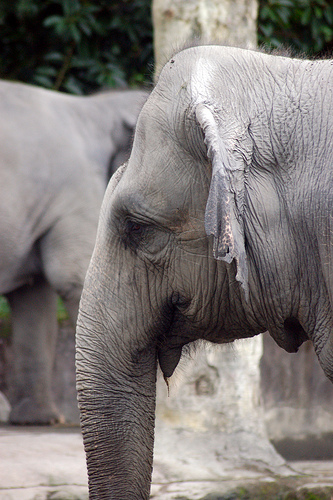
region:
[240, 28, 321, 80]
hair growing on elephant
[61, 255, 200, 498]
trunk of an elephant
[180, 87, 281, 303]
elephant's ear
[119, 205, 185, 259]
open eye on gray elephant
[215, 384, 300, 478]
rock formulations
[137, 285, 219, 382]
elephant's mouth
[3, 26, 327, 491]
close up picture with elephant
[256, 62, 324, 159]
very wrinkled skin on elephant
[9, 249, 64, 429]
foot of an gray elephant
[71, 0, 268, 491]
trunk of tree behind elephant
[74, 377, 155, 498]
An elephant's trunk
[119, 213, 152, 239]
An elephant's eye ball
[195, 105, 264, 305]
An elephant's left ear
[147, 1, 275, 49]
A tree trunk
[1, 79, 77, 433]
An elephant facing right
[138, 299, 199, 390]
The mouth of an elephant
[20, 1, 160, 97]
Leaves on a bush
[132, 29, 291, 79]
Hair on an elephant's head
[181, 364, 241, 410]
Knot on a tree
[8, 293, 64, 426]
An elephant's left front leg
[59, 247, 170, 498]
This is an elephant's trunk.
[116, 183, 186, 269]
This is an elephant's eye.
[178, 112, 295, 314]
This is an elephant's ear.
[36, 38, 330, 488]
This is an elephant's head.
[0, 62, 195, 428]
This is an elephant.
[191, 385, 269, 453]
This is a tree trunk.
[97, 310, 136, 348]
This is the color gray.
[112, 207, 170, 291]
This is the eye of an elephant.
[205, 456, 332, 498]
These are green weeds.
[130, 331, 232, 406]
This is an elephant's mouth.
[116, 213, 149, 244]
the eye of an elephant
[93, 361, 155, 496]
the trunk of an elephant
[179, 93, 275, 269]
the ear of an elephant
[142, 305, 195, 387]
the mouth of an elephant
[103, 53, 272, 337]
the head of an elephant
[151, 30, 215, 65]
hair on an elephants head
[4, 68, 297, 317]
two elephants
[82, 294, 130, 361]
wrinkles in a elephant's skin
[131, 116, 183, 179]
forehead of an elephant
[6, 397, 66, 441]
the foot of an elephant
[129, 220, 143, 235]
the eye of an elephant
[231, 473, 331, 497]
patches of green grass on the ground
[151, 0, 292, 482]
a white tree trunk behind the elephant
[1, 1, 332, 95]
green leaves of a tree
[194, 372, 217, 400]
a knot on the tree trunk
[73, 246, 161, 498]
the elephant's trunk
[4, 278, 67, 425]
an elephant's leg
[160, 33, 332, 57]
the hair on the elephant's head